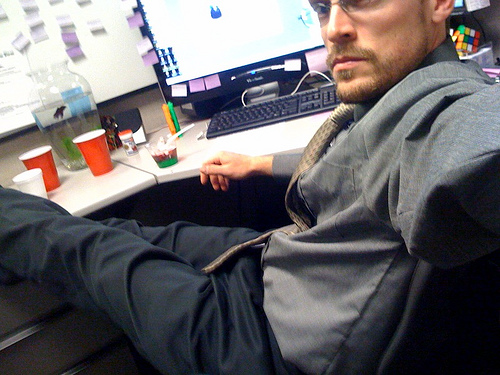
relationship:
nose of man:
[310, 7, 354, 36] [316, 19, 430, 218]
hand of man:
[204, 131, 243, 167] [316, 19, 430, 218]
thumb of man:
[204, 158, 234, 185] [316, 19, 430, 218]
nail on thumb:
[197, 157, 218, 165] [204, 158, 234, 185]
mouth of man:
[308, 32, 400, 101] [316, 19, 430, 218]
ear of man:
[423, 2, 462, 29] [316, 19, 430, 218]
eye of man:
[310, 7, 354, 36] [316, 19, 430, 218]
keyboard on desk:
[204, 97, 331, 135] [172, 135, 247, 170]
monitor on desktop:
[147, 6, 287, 100] [168, 32, 331, 139]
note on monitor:
[134, 23, 254, 102] [147, 6, 287, 100]